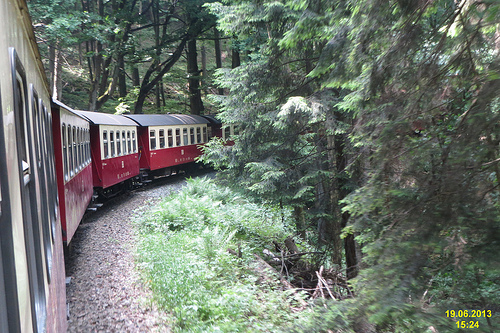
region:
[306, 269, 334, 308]
Sticks piled in front of a tree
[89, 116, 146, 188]
Red passenger train car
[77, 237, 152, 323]
Gravel on a train track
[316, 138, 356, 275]
Tree trunks in the forest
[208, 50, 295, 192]
Green leaves on a tree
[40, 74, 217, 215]
Train cars rounding a bend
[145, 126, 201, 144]
White windows on a train car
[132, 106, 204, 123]
Grey roof on a train car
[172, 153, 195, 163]
Gold lettering on a red train car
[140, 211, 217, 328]
Sun shining on grass in a forest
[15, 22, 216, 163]
train ride on the tracks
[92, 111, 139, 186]
red and white train car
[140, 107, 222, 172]
red and white train car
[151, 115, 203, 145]
windows on the train car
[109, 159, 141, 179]
words on the train car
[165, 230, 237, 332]
grass on the ground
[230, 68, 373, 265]
trees next to the train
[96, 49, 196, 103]
tree trunks behind the track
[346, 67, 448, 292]
branches on a pine tree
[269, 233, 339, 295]
branches on the ground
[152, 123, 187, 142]
Windows on the train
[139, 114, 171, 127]
roof of the train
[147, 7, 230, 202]
The green grass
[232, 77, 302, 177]
leaves of the trees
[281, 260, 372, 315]
tree branches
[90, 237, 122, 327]
rocks on the ground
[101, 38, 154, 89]
tree trunks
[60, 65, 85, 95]
dirt on the ground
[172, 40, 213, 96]
a tree trunk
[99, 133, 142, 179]
train is red and white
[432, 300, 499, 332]
Date on the train.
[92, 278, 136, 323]
Gravel next to the tracks.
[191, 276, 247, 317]
The grass is green.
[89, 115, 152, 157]
White around the windows.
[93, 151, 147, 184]
The train car is red.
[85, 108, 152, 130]
Roof of the train car is black.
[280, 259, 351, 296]
Twigs on the ground.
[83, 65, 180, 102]
The trunks are black.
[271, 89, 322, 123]
Sun shining on the leaves.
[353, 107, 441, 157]
Brown in the leaves.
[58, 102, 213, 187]
THE TRAIN HAS MANY WINDOWS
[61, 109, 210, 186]
THE WINDOWS HAVE WHITE TRIM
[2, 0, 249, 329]
THE TRAIN IS RED AND WHITE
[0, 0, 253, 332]
THE TRAIN HAS MANY CARS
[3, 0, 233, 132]
THE TRAIN CARS HAVE BLACK TOPS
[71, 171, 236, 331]
THE GRAVEL IS BY THE TRACKS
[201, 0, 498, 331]
THE GREEN TREES ARE TALL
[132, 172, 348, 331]
THE WEEDS ARE GREEN AND HIGH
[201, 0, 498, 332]
THE TREES ARE EVERGREEN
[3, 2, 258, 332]
THE TRAIN IS ON A CURVE